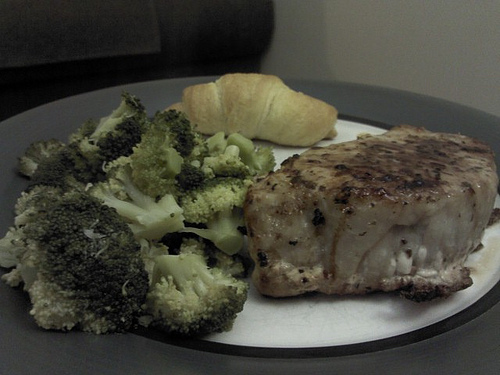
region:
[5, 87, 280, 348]
Broccoli is on the plate.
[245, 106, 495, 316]
Meat is on the plate.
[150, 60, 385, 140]
A croissont is on the plate.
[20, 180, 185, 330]
A piece of broccoli.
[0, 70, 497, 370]
A plate of food.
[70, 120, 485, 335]
The plate has a white center.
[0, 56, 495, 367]
The plate has a grey rim.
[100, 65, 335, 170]
A croissont next to broccoli.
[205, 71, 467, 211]
A croissont next to meat.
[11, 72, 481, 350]
Three different types of food.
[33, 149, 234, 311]
The broccoli is green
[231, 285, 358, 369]
The plate is white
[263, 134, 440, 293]
The meat has seasonings on it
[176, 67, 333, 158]
The roll is brown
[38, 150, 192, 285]
The broccoli is cooked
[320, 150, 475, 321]
The meat is cooked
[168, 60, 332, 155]
The roll is rolled up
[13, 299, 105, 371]
The plate has a gray outter ring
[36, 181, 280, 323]
Some parts of the broccoli is light green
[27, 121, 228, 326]
This is a vegetable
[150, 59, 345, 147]
A crousaint on the white plate.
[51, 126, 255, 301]
Broccoli on the plate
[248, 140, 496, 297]
A piece of meat on the white plate.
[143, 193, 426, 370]
The plate is white.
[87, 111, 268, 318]
The broccoli is green.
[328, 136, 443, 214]
The meat has pepper on it.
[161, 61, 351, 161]
The croissant is toasted.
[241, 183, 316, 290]
The meat have fat on the end of it.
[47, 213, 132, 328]
The broccoli has florets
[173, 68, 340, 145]
A small croissant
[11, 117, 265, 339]
A large serving of broccoli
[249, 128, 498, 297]
A slice of boneless pork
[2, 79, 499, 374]
Food on a grey and white plate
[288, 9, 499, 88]
A white wall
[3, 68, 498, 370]
Grey edge on a dinner plate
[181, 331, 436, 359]
A decorative black band on a dinner plate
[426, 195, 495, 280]
Fat on a pork chop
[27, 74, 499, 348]
A dinner with bread, meat and vegetables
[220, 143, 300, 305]
Broccoli touching a portion of pork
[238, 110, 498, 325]
The meat on the plate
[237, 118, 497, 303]
The meat is seared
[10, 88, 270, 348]
The broccoli on the plate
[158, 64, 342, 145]
The flaky croissant on the plate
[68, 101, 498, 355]
the plate is white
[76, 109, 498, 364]
the plate on the table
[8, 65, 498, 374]
the table is gray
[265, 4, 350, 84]
the shadow on the wall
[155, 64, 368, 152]
the croissant is toasted